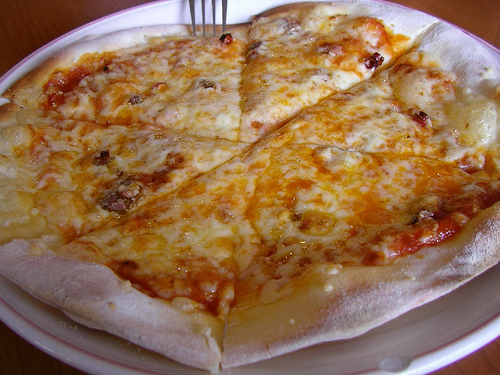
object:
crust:
[0, 244, 219, 375]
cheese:
[90, 93, 263, 211]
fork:
[184, 0, 228, 42]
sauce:
[397, 209, 459, 253]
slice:
[0, 22, 255, 145]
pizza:
[3, 0, 499, 374]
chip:
[379, 352, 414, 374]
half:
[0, 0, 443, 274]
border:
[0, 0, 175, 77]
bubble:
[315, 142, 361, 179]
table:
[0, 0, 500, 373]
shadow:
[28, 279, 490, 365]